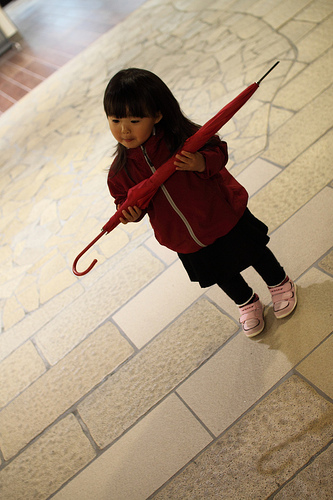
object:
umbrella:
[72, 60, 280, 277]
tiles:
[1, 0, 146, 115]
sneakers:
[267, 275, 298, 318]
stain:
[257, 413, 330, 479]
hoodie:
[107, 117, 249, 254]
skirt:
[176, 206, 270, 289]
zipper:
[141, 144, 207, 248]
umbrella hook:
[72, 228, 108, 276]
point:
[256, 61, 280, 86]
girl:
[103, 68, 297, 338]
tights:
[215, 244, 285, 306]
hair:
[103, 68, 224, 179]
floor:
[0, 0, 332, 500]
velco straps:
[269, 282, 292, 303]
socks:
[236, 289, 257, 309]